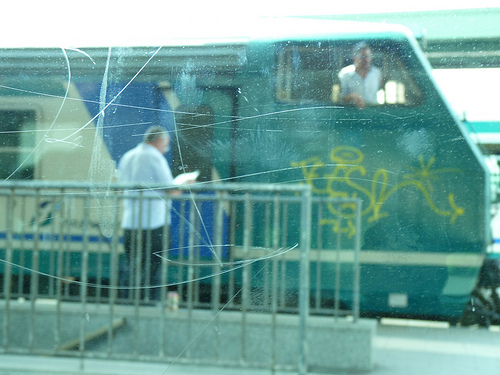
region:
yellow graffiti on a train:
[265, 125, 484, 257]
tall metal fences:
[13, 161, 363, 357]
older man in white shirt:
[108, 112, 197, 288]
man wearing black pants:
[108, 113, 179, 294]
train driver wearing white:
[329, 41, 414, 119]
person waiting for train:
[108, 121, 210, 295]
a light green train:
[6, 37, 497, 339]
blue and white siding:
[12, 70, 237, 263]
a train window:
[6, 97, 48, 191]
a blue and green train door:
[147, 79, 239, 281]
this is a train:
[0, 18, 491, 293]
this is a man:
[114, 123, 184, 290]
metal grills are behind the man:
[6, 184, 350, 372]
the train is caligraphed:
[290, 148, 467, 246]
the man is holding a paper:
[173, 168, 201, 194]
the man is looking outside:
[331, 43, 390, 104]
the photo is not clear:
[5, 2, 491, 374]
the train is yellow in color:
[2, 23, 469, 315]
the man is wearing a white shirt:
[121, 146, 169, 231]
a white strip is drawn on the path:
[376, 333, 482, 347]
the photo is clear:
[8, 54, 498, 359]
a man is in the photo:
[96, 117, 233, 330]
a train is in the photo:
[8, 56, 497, 322]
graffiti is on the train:
[283, 132, 488, 269]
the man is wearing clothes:
[93, 125, 211, 327]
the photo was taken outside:
[2, 52, 498, 349]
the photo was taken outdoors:
[1, 32, 497, 365]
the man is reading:
[99, 117, 251, 307]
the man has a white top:
[93, 125, 200, 248]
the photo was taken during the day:
[5, 47, 497, 362]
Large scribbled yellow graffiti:
[297, 145, 463, 235]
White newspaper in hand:
[175, 170, 200, 182]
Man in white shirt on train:
[332, 40, 377, 106]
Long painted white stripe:
[232, 246, 477, 261]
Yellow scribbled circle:
[330, 140, 365, 165]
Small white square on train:
[385, 290, 410, 305]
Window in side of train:
[0, 97, 45, 182]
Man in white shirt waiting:
[110, 120, 185, 295]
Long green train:
[0, 27, 476, 307]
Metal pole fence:
[1, 175, 311, 371]